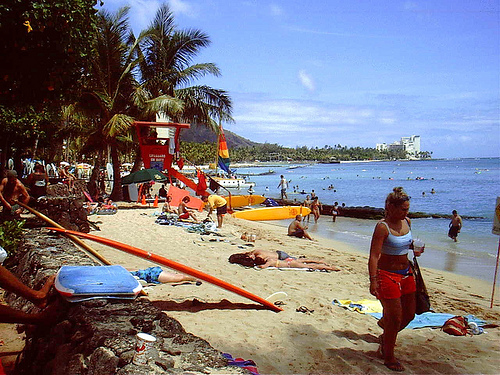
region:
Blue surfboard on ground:
[59, 260, 137, 303]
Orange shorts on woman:
[377, 266, 419, 297]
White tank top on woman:
[375, 221, 419, 255]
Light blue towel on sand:
[384, 308, 484, 325]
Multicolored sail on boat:
[217, 121, 232, 173]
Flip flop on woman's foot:
[385, 360, 402, 370]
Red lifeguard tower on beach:
[137, 118, 189, 170]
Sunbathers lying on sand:
[226, 248, 341, 270]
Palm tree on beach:
[132, 6, 229, 125]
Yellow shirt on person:
[207, 192, 222, 209]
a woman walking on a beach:
[323, 177, 446, 374]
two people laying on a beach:
[224, 243, 329, 271]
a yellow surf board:
[239, 200, 310, 222]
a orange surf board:
[36, 209, 283, 328]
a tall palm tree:
[119, 17, 205, 192]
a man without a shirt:
[0, 160, 24, 222]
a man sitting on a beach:
[288, 208, 314, 237]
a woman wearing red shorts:
[361, 187, 423, 317]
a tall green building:
[390, 127, 430, 165]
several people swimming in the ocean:
[295, 152, 477, 199]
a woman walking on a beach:
[366, 188, 424, 374]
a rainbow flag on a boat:
[216, 122, 236, 172]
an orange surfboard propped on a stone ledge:
[45, 220, 280, 311]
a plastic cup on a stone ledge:
[130, 326, 155, 362]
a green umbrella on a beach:
[121, 165, 166, 210]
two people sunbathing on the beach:
[244, 247, 341, 272]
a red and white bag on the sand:
[442, 312, 470, 338]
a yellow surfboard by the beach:
[236, 204, 311, 221]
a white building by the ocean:
[374, 134, 420, 161]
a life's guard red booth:
[133, 120, 234, 217]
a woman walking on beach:
[364, 185, 436, 369]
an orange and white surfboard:
[43, 221, 290, 314]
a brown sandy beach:
[59, 193, 496, 372]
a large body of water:
[200, 160, 497, 252]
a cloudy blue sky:
[106, 0, 499, 158]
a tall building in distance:
[398, 135, 420, 160]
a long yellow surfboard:
[232, 204, 311, 221]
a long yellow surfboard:
[222, 193, 268, 208]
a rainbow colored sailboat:
[204, 124, 242, 181]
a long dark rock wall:
[12, 217, 249, 369]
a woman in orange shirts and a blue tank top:
[364, 184, 435, 373]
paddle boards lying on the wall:
[50, 258, 145, 304]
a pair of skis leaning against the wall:
[9, 197, 282, 329]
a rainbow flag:
[212, 118, 234, 177]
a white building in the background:
[373, 133, 426, 160]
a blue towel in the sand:
[366, 308, 490, 335]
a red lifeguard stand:
[125, 118, 235, 214]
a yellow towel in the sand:
[331, 292, 384, 314]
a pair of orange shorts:
[367, 263, 418, 302]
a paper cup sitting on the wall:
[126, 330, 157, 368]